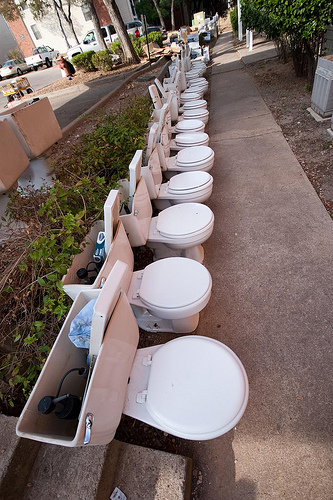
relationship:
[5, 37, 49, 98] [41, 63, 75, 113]
wagon on street